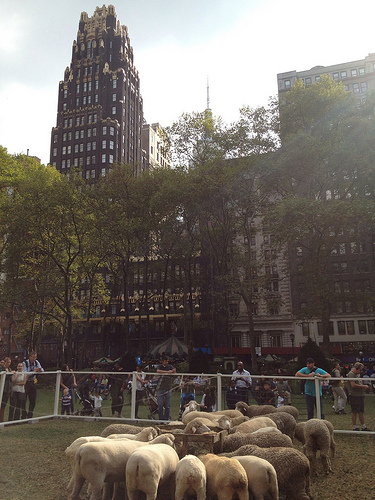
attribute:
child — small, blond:
[59, 387, 73, 415]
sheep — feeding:
[126, 443, 181, 499]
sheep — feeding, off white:
[175, 454, 208, 499]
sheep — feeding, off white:
[69, 432, 177, 499]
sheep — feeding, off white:
[197, 452, 250, 498]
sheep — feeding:
[230, 455, 281, 499]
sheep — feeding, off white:
[217, 443, 315, 499]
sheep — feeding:
[223, 431, 295, 452]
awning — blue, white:
[145, 335, 189, 356]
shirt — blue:
[298, 366, 329, 397]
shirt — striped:
[61, 393, 73, 406]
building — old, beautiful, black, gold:
[50, 3, 144, 192]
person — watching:
[154, 355, 178, 421]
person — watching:
[231, 361, 253, 405]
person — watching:
[296, 357, 334, 421]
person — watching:
[9, 361, 28, 420]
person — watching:
[22, 350, 46, 420]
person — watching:
[1, 357, 14, 423]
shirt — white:
[231, 368, 254, 388]